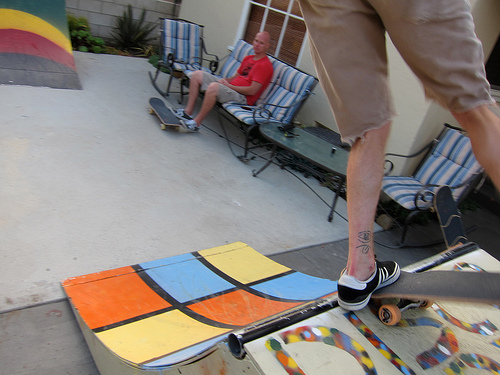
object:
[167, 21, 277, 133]
man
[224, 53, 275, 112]
shirt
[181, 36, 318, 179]
couch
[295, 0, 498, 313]
man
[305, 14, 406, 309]
leg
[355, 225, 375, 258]
tattoo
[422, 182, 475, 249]
skateboard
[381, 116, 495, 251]
chair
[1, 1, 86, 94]
skateboard ramp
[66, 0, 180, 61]
wall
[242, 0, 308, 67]
window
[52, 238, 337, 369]
skateboard ramp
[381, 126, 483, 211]
cushion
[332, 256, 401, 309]
sneaker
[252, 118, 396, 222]
coffee table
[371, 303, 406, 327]
skateboard wheel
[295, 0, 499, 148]
shorts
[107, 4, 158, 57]
plant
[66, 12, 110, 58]
plant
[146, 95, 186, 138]
skateboard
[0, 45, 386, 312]
concrete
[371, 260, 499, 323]
skateboard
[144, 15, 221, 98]
rocking chair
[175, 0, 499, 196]
wall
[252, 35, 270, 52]
face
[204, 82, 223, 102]
knee